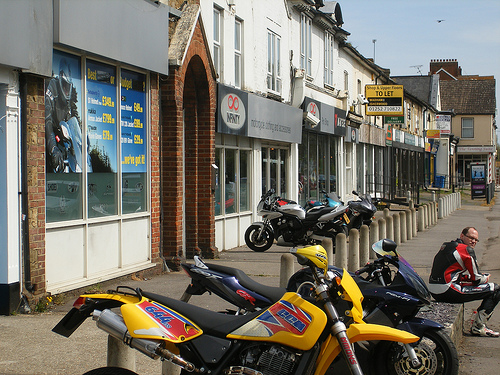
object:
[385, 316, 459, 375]
tire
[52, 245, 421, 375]
bike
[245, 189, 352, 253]
bike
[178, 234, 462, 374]
bike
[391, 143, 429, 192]
ground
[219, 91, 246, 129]
sign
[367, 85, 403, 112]
words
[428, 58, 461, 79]
brick chimney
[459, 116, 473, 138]
window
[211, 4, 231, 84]
window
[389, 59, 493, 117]
roof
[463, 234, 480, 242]
glasses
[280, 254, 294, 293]
barrier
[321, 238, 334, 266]
barrier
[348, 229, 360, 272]
barrier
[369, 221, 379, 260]
barrier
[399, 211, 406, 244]
barrier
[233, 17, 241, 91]
windows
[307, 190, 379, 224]
motorbike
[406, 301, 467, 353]
curb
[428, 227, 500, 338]
gear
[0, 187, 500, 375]
floor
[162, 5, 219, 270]
archway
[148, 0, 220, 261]
brick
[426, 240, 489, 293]
jacket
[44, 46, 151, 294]
doors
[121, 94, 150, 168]
words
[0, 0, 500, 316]
building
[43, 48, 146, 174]
poster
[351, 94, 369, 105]
camera